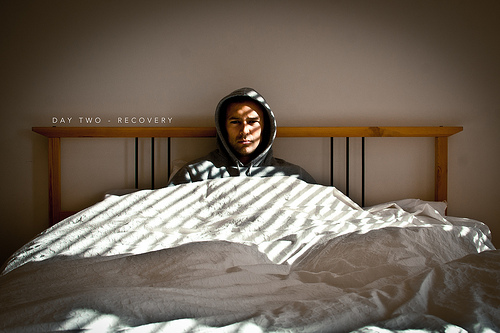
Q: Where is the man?
A: In bed.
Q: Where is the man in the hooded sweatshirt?
A: Under the blankets.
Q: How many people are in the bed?
A: One.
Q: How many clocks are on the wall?
A: Zero.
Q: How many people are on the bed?
A: One.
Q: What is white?
A: Bed sheets.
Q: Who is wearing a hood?
A: The man.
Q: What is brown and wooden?
A: Headboard.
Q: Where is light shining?
A: On the bed sheets.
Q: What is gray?
A: Man's hoodie.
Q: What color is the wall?
A: White.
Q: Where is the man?
A: In bed.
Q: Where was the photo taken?
A: In a bedroom.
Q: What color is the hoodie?
A: Grey.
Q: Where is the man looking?
A: At the camera.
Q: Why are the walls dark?
A: Painted brownish grey.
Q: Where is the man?
A: In bed.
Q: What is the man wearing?
A: A hoodie.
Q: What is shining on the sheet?
A: Sun.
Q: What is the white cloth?
A: Bedspread.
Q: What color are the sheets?
A: White.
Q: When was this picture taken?
A: Daytime.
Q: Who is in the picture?
A: A man.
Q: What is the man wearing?
A: A hoodie.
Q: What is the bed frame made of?
A: Wood.